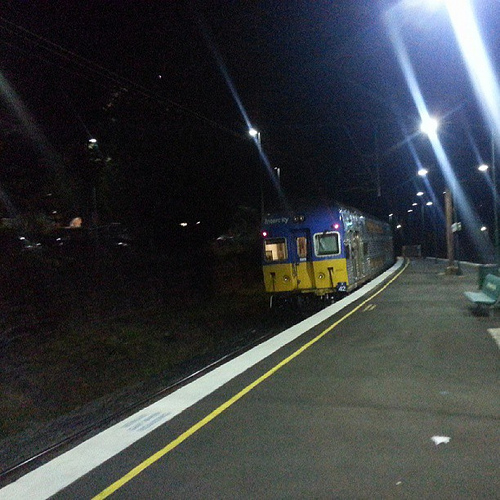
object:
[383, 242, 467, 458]
train platform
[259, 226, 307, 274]
light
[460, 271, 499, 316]
bench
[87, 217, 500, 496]
street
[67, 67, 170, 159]
lights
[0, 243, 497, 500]
floor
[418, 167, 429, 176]
light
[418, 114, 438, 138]
light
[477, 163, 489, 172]
light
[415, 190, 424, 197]
light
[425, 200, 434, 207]
light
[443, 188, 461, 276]
post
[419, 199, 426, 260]
post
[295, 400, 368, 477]
floor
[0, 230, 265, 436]
grass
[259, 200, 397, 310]
train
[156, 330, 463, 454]
road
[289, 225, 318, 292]
door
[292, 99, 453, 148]
ground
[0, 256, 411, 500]
stripe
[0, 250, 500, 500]
platform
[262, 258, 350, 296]
yellow section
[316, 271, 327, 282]
headlight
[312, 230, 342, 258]
window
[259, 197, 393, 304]
area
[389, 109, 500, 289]
street lights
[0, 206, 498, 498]
area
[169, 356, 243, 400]
line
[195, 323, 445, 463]
platform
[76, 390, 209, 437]
edge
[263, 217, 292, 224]
writing